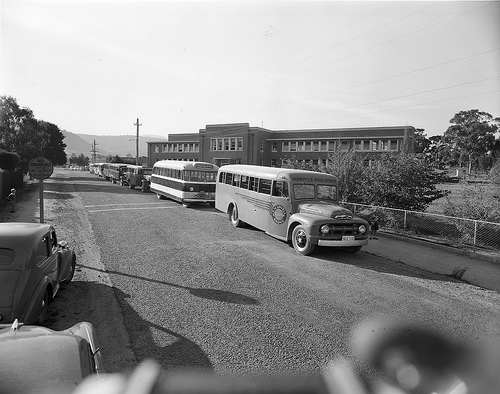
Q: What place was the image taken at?
A: It was taken at the street.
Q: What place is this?
A: It is a street.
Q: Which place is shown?
A: It is a street.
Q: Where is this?
A: This is at the street.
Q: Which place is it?
A: It is a street.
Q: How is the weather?
A: It is cloudy.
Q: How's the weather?
A: It is cloudy.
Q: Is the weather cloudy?
A: Yes, it is cloudy.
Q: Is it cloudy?
A: Yes, it is cloudy.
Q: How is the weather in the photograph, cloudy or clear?
A: It is cloudy.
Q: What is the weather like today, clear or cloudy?
A: It is cloudy.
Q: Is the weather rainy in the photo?
A: No, it is cloudy.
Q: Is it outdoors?
A: Yes, it is outdoors.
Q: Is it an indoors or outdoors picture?
A: It is outdoors.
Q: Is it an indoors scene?
A: No, it is outdoors.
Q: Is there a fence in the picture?
A: Yes, there is a fence.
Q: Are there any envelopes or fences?
A: Yes, there is a fence.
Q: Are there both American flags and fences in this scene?
A: No, there is a fence but no American flags.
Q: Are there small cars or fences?
A: Yes, there is a small fence.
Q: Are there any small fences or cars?
A: Yes, there is a small fence.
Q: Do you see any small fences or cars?
A: Yes, there is a small fence.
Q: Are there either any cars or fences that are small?
A: Yes, the fence is small.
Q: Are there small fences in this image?
A: Yes, there is a small fence.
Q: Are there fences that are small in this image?
A: Yes, there is a small fence.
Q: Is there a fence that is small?
A: Yes, there is a fence that is small.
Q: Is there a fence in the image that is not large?
A: Yes, there is a small fence.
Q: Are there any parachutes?
A: No, there are no parachutes.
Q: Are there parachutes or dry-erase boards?
A: No, there are no parachutes or dry-erase boards.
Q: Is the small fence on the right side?
A: Yes, the fence is on the right of the image.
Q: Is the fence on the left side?
A: No, the fence is on the right of the image.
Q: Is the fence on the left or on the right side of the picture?
A: The fence is on the right of the image.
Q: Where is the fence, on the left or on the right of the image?
A: The fence is on the right of the image.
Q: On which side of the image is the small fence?
A: The fence is on the right of the image.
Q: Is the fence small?
A: Yes, the fence is small.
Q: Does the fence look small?
A: Yes, the fence is small.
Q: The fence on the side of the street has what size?
A: The fence is small.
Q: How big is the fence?
A: The fence is small.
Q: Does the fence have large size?
A: No, the fence is small.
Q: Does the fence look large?
A: No, the fence is small.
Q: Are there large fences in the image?
A: No, there is a fence but it is small.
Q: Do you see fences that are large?
A: No, there is a fence but it is small.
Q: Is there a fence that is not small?
A: No, there is a fence but it is small.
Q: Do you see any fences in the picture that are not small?
A: No, there is a fence but it is small.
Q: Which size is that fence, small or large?
A: The fence is small.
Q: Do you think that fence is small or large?
A: The fence is small.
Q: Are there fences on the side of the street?
A: Yes, there is a fence on the side of the street.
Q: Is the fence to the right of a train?
A: No, the fence is to the right of the bus.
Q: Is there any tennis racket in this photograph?
A: No, there are no rackets.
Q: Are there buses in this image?
A: Yes, there is a bus.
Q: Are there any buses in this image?
A: Yes, there is a bus.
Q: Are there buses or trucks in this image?
A: Yes, there is a bus.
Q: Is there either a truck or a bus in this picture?
A: Yes, there is a bus.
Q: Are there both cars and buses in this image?
A: Yes, there are both a bus and a car.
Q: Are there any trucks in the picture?
A: No, there are no trucks.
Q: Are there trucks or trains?
A: No, there are no trucks or trains.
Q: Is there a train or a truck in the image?
A: No, there are no trucks or trains.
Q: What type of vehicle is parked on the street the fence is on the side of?
A: The vehicle is a bus.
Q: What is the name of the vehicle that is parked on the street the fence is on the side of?
A: The vehicle is a bus.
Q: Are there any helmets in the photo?
A: No, there are no helmets.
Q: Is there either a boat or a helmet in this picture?
A: No, there are no helmets or boats.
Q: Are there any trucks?
A: No, there are no trucks.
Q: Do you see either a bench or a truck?
A: No, there are no trucks or benches.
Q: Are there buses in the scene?
A: Yes, there is a bus.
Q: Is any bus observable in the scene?
A: Yes, there is a bus.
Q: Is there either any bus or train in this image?
A: Yes, there is a bus.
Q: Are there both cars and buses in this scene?
A: Yes, there are both a bus and a car.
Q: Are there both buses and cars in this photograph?
A: Yes, there are both a bus and a car.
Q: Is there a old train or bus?
A: Yes, there is an old bus.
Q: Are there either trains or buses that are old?
A: Yes, the bus is old.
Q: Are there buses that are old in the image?
A: Yes, there is an old bus.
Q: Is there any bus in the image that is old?
A: Yes, there is a bus that is old.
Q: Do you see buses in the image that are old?
A: Yes, there is a bus that is old.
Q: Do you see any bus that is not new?
A: Yes, there is a old bus.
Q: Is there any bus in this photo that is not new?
A: Yes, there is a old bus.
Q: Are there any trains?
A: No, there are no trains.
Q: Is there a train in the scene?
A: No, there are no trains.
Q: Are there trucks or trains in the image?
A: No, there are no trains or trucks.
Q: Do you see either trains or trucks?
A: No, there are no trains or trucks.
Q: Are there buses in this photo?
A: Yes, there is a bus.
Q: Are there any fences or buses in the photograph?
A: Yes, there is a bus.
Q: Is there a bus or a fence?
A: Yes, there is a bus.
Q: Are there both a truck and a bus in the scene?
A: No, there is a bus but no trucks.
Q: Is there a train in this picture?
A: No, there are no trains.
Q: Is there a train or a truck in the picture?
A: No, there are no trains or trucks.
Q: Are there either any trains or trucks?
A: No, there are no trains or trucks.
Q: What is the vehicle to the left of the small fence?
A: The vehicle is a bus.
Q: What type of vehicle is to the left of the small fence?
A: The vehicle is a bus.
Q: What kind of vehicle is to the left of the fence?
A: The vehicle is a bus.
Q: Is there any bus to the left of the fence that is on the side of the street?
A: Yes, there is a bus to the left of the fence.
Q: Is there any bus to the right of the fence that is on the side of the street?
A: No, the bus is to the left of the fence.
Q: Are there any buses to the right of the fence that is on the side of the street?
A: No, the bus is to the left of the fence.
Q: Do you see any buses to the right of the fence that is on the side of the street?
A: No, the bus is to the left of the fence.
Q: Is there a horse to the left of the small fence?
A: No, there is a bus to the left of the fence.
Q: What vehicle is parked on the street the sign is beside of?
A: The vehicle is a bus.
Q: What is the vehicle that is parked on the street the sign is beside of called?
A: The vehicle is a bus.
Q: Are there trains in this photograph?
A: No, there are no trains.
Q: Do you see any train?
A: No, there are no trains.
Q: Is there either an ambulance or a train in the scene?
A: No, there are no trains or ambulances.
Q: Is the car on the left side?
A: Yes, the car is on the left of the image.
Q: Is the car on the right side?
A: No, the car is on the left of the image.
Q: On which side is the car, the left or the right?
A: The car is on the left of the image.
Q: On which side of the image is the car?
A: The car is on the left of the image.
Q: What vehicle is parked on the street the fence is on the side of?
A: The vehicle is a car.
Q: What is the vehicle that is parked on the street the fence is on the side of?
A: The vehicle is a car.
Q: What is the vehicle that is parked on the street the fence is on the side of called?
A: The vehicle is a car.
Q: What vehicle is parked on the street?
A: The vehicle is a car.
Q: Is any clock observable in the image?
A: No, there are no clocks.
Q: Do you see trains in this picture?
A: No, there are no trains.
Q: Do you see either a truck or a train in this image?
A: No, there are no trains or trucks.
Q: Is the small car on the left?
A: Yes, the car is on the left of the image.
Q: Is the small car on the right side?
A: No, the car is on the left of the image.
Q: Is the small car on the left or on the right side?
A: The car is on the left of the image.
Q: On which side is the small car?
A: The car is on the left of the image.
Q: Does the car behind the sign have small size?
A: Yes, the car is small.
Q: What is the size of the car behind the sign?
A: The car is small.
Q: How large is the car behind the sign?
A: The car is small.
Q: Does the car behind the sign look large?
A: No, the car is small.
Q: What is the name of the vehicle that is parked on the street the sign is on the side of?
A: The vehicle is a car.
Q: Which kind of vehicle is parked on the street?
A: The vehicle is a car.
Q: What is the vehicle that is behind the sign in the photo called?
A: The vehicle is a car.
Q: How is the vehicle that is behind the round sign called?
A: The vehicle is a car.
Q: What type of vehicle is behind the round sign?
A: The vehicle is a car.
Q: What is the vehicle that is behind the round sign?
A: The vehicle is a car.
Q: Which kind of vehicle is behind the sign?
A: The vehicle is a car.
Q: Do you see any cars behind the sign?
A: Yes, there is a car behind the sign.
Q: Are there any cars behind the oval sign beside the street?
A: Yes, there is a car behind the sign.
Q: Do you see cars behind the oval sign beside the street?
A: Yes, there is a car behind the sign.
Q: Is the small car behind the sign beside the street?
A: Yes, the car is behind the sign.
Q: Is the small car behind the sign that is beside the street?
A: Yes, the car is behind the sign.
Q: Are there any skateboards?
A: No, there are no skateboards.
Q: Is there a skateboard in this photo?
A: No, there are no skateboards.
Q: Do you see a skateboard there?
A: No, there are no skateboards.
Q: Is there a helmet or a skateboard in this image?
A: No, there are no skateboards or helmets.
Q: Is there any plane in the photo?
A: No, there are no airplanes.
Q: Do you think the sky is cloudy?
A: Yes, the sky is cloudy.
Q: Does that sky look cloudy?
A: Yes, the sky is cloudy.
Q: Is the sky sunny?
A: No, the sky is cloudy.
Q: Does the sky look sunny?
A: No, the sky is cloudy.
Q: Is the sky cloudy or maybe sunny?
A: The sky is cloudy.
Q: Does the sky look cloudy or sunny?
A: The sky is cloudy.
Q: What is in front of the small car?
A: The sign is in front of the car.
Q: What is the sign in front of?
A: The sign is in front of the car.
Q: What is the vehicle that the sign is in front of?
A: The vehicle is a car.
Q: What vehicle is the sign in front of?
A: The sign is in front of the car.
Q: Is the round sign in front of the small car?
A: Yes, the sign is in front of the car.